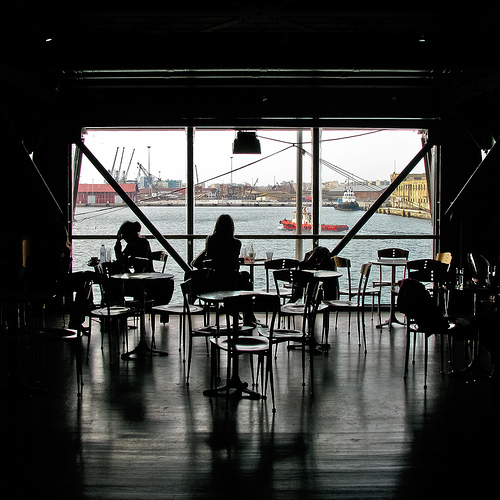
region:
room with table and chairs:
[43, 233, 495, 412]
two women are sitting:
[97, 193, 261, 285]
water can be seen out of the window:
[91, 199, 416, 279]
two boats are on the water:
[268, 175, 375, 235]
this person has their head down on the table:
[281, 238, 346, 317]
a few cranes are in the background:
[105, 139, 159, 186]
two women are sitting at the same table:
[33, 215, 170, 350]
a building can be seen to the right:
[393, 163, 429, 224]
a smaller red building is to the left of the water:
[72, 178, 143, 208]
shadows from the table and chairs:
[208, 390, 334, 491]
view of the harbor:
[70, 120, 495, 312]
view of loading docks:
[84, 130, 455, 310]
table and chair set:
[180, 266, 316, 397]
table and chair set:
[265, 253, 355, 347]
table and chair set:
[360, 240, 452, 300]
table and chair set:
[11, 248, 91, 361]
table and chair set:
[394, 253, 490, 335]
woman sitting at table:
[184, 199, 257, 320]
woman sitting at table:
[86, 210, 181, 327]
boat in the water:
[264, 189, 363, 242]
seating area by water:
[39, 211, 474, 381]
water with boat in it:
[82, 200, 433, 287]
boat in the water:
[280, 199, 347, 238]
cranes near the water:
[104, 139, 136, 178]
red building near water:
[79, 180, 140, 205]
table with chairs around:
[176, 277, 309, 399]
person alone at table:
[193, 210, 271, 277]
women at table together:
[41, 203, 168, 291]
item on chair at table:
[386, 283, 451, 328]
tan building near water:
[381, 170, 433, 215]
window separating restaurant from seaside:
[20, 40, 486, 466]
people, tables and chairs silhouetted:
[52, 110, 462, 430]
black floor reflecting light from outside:
[36, 300, 478, 490]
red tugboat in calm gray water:
[245, 205, 367, 265]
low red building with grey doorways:
[80, 175, 135, 205]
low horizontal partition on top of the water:
[135, 195, 335, 210]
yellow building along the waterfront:
[380, 166, 425, 213]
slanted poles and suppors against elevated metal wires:
[70, 130, 430, 290]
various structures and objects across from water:
[111, 145, 306, 205]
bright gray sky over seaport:
[80, 135, 425, 183]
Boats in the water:
[281, 190, 357, 229]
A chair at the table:
[213, 300, 277, 397]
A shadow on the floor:
[207, 398, 282, 498]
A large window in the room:
[77, 128, 431, 305]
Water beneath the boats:
[74, 206, 431, 303]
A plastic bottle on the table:
[98, 244, 105, 262]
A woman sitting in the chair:
[206, 215, 258, 328]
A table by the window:
[371, 257, 417, 330]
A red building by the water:
[75, 185, 138, 202]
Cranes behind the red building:
[106, 147, 138, 181]